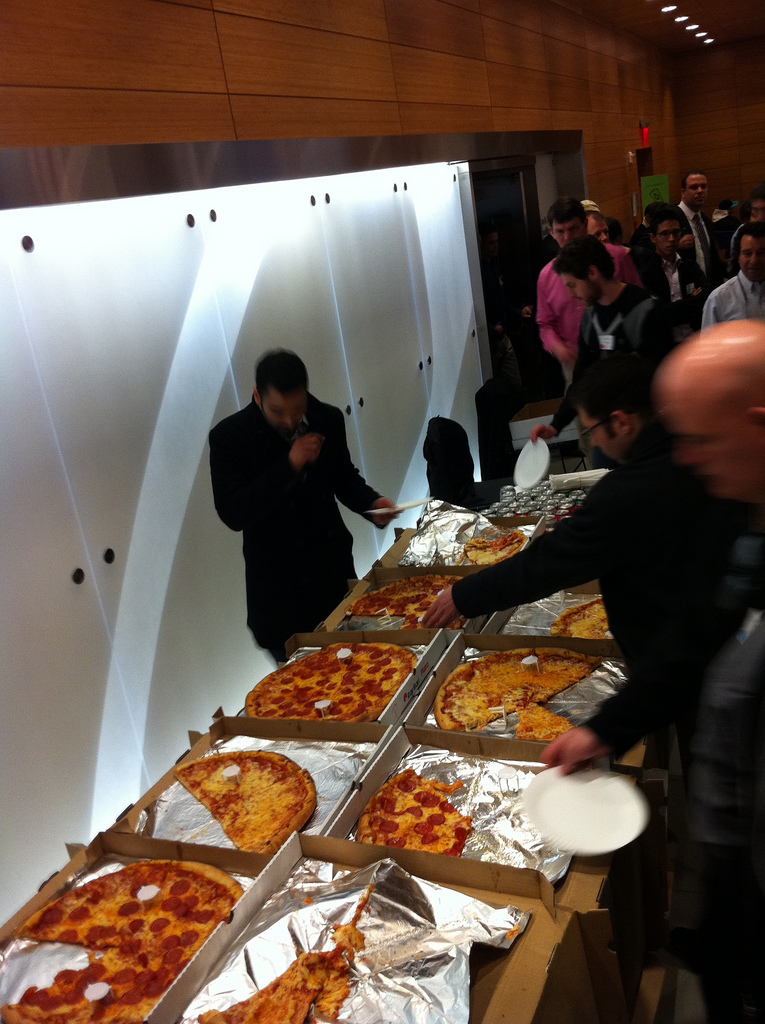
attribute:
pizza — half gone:
[171, 753, 318, 847]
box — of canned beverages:
[483, 470, 604, 525]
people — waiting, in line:
[530, 171, 737, 369]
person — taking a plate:
[501, 237, 673, 495]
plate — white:
[536, 773, 629, 855]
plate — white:
[515, 769, 649, 860]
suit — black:
[206, 395, 388, 659]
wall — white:
[0, 152, 492, 930]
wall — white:
[40, 678, 91, 761]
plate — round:
[534, 771, 632, 860]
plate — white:
[499, 754, 663, 841]